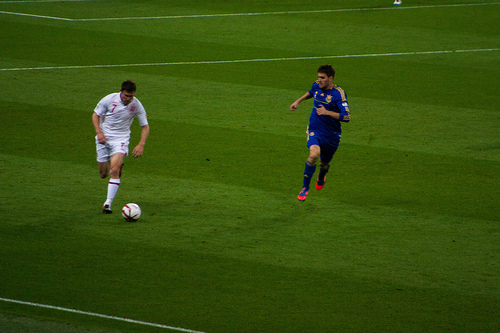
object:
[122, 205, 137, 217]
stripes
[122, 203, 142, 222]
ball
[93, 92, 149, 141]
jersey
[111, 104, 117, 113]
number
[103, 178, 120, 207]
sock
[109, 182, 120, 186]
stripe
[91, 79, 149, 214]
man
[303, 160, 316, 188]
socks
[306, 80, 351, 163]
uniform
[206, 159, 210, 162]
patch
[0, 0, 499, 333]
field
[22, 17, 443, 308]
soccer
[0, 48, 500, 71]
line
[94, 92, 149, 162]
uniform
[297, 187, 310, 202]
shoes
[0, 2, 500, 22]
lines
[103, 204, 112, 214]
shoes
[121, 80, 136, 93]
hair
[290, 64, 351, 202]
man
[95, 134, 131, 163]
shorts